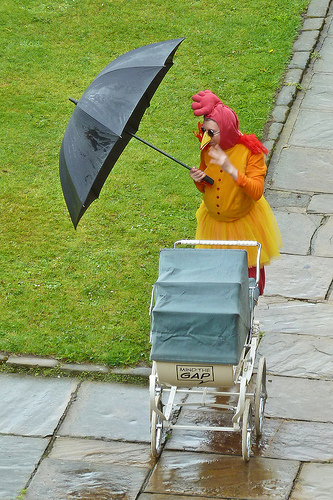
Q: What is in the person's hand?
A: An umbrella.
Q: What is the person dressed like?
A: A chicken.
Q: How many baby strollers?
A: One.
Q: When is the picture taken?
A: Daytime.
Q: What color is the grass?
A: Green.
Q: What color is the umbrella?
A: Black.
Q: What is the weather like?
A: Rainy.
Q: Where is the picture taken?
A: On a sidewalk by the grass.